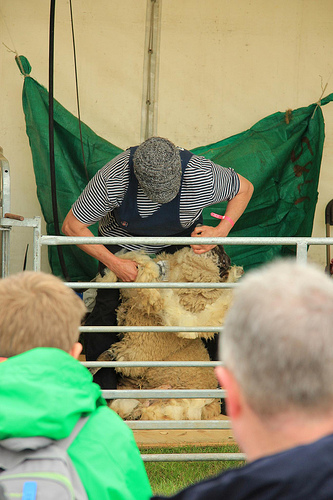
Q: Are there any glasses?
A: No, there are no glasses.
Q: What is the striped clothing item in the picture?
A: The clothing item is a shirt.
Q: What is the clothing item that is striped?
A: The clothing item is a shirt.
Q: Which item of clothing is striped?
A: The clothing item is a shirt.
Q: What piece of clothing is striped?
A: The clothing item is a shirt.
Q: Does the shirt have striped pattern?
A: Yes, the shirt is striped.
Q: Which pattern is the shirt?
A: The shirt is striped.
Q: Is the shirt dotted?
A: No, the shirt is striped.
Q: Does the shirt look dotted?
A: No, the shirt is striped.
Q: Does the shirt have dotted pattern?
A: No, the shirt is striped.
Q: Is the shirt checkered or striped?
A: The shirt is striped.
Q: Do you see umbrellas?
A: No, there are no umbrellas.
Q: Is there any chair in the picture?
A: No, there are no chairs.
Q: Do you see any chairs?
A: No, there are no chairs.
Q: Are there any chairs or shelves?
A: No, there are no chairs or shelves.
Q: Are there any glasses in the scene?
A: No, there are no glasses.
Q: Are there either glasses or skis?
A: No, there are no glasses or skis.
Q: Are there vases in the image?
A: No, there are no vases.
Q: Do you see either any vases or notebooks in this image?
A: No, there are no vases or notebooks.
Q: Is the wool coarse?
A: Yes, the wool is coarse.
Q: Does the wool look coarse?
A: Yes, the wool is coarse.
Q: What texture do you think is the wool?
A: The wool is coarse.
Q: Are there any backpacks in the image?
A: Yes, there is a backpack.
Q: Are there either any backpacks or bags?
A: Yes, there is a backpack.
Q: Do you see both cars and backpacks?
A: No, there is a backpack but no cars.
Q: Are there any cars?
A: No, there are no cars.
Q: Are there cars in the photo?
A: No, there are no cars.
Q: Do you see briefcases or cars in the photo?
A: No, there are no cars or briefcases.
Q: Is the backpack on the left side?
A: Yes, the backpack is on the left of the image.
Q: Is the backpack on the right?
A: No, the backpack is on the left of the image.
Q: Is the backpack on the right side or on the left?
A: The backpack is on the left of the image.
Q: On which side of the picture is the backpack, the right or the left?
A: The backpack is on the left of the image.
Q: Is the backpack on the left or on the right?
A: The backpack is on the left of the image.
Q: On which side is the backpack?
A: The backpack is on the left of the image.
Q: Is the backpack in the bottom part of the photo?
A: Yes, the backpack is in the bottom of the image.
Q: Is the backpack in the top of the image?
A: No, the backpack is in the bottom of the image.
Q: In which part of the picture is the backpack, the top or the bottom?
A: The backpack is in the bottom of the image.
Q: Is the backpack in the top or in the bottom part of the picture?
A: The backpack is in the bottom of the image.